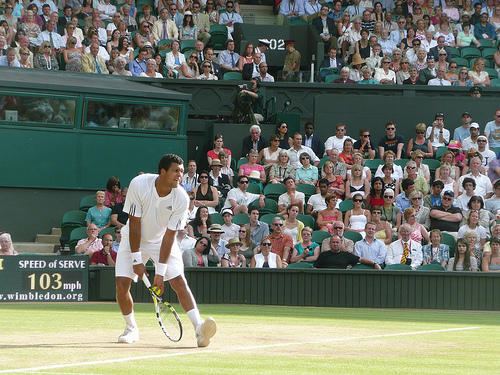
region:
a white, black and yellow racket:
[137, 267, 188, 344]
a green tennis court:
[0, 275, 497, 373]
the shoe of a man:
[190, 318, 220, 347]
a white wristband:
[152, 261, 167, 278]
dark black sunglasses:
[240, 175, 253, 185]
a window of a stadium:
[87, 96, 182, 133]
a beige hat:
[207, 223, 223, 235]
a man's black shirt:
[316, 246, 362, 270]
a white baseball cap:
[466, 121, 483, 129]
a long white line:
[0, 314, 499, 373]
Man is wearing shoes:
[112, 317, 215, 348]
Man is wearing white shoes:
[117, 314, 217, 348]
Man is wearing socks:
[118, 306, 204, 332]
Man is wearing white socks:
[121, 305, 205, 330]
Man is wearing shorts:
[112, 232, 186, 283]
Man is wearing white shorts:
[112, 232, 185, 282]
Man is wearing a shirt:
[120, 172, 190, 250]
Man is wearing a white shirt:
[120, 171, 187, 253]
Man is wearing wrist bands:
[128, 245, 168, 280]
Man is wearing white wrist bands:
[126, 245, 169, 276]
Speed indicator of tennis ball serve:
[22, 270, 89, 296]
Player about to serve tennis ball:
[110, 154, 220, 352]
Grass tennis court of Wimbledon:
[6, 317, 494, 372]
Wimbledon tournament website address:
[2, 290, 85, 307]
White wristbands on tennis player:
[123, 252, 174, 279]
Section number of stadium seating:
[261, 35, 289, 55]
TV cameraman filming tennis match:
[226, 77, 268, 124]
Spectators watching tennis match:
[5, 5, 495, 102]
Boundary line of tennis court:
[4, 316, 494, 370]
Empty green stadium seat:
[58, 208, 90, 249]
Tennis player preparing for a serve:
[114, 152, 216, 348]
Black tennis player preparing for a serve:
[113, 153, 218, 348]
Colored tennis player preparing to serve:
[113, 151, 216, 347]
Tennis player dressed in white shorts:
[113, 153, 216, 349]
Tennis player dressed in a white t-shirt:
[113, 154, 218, 349]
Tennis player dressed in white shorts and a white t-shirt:
[113, 152, 217, 346]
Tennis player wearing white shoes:
[113, 152, 217, 352]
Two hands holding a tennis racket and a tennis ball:
[130, 250, 183, 344]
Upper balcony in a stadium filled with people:
[0, 0, 496, 92]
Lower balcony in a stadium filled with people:
[190, 103, 499, 273]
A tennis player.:
[109, 151, 229, 348]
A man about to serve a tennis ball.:
[109, 148, 219, 349]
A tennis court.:
[0, 300, 495, 370]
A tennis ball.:
[150, 280, 165, 292]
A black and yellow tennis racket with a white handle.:
[130, 265, 180, 335]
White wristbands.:
[129, 248, 166, 278]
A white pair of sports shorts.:
[114, 232, 184, 280]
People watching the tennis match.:
[1, 2, 498, 270]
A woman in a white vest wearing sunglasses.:
[249, 237, 284, 268]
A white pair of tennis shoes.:
[115, 317, 220, 351]